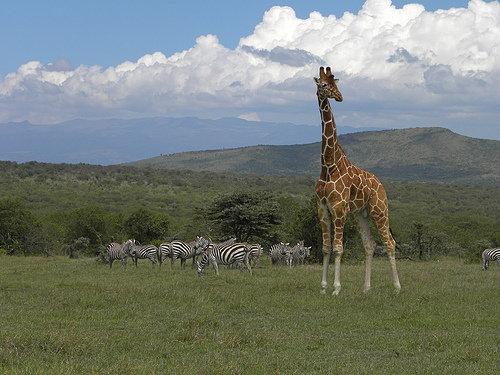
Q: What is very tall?
A: The giraffe.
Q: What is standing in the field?
A: The giraffe.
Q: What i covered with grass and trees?
A: The hillside.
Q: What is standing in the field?
A: The zebra's and giraffe.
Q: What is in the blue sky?
A: The white clouds.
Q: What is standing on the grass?
A: The giraffe.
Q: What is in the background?
A: The herd of zebras.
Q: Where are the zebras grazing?
A: In grass.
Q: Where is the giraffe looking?
A: To the right.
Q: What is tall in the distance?
A: Mountains.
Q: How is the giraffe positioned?
A: Standing.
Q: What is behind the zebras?
A: Trees.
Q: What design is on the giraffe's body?
A: Brown and white spots.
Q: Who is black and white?
A: Zebras.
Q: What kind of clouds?
A: Thick.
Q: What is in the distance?
A: Trees.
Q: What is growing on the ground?
A: Grass.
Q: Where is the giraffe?
A: Grass.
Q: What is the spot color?
A: Brown.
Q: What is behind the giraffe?
A: Zebras.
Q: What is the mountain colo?
A: Brown.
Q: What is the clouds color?
A: Grey.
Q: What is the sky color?
A: Blue.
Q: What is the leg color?
A: White.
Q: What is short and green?
A: Grass.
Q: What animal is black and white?
A: Zebra.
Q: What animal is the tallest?
A: Giraffe.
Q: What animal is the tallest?
A: Giraffe.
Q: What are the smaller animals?
A: Zebras.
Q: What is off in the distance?
A: Mountains.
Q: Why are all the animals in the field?
A: To eat the grass.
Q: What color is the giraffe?
A: Tan and brown.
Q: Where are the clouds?
A: In the sky.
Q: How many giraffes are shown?
A: 1.